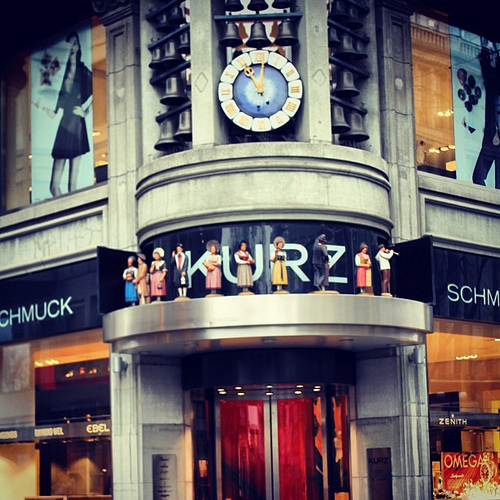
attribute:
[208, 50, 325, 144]
clock — gold, blue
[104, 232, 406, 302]
statues — little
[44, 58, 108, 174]
dress — black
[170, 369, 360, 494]
door — glass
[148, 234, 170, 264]
hat — white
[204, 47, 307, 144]
clock — small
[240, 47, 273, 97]
clock hand — small, golden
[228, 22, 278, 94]
clock hand — large, golden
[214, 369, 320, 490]
curtains — red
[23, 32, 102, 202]
picture — large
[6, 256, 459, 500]
picture — large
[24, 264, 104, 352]
writing — white 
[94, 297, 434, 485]
entrance — store 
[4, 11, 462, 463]
building — top , side  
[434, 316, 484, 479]
window — store 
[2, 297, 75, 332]
logo's — name brand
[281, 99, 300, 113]
numerals — roman 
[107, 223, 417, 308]
awing — top 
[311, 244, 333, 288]
coat — black 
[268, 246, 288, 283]
dress — yellow 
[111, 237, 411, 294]
awing — top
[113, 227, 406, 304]
awing — top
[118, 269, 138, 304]
dress — blue 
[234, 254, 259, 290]
dress — grey 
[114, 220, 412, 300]
awing — top 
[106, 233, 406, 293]
awing — top 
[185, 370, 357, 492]
entryway — Glass door 